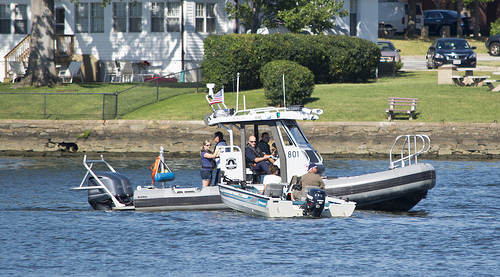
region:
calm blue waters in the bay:
[30, 217, 130, 243]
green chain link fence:
[51, 84, 142, 115]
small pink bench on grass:
[373, 83, 432, 118]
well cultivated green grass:
[333, 80, 393, 97]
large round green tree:
[257, 53, 318, 113]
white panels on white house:
[85, 29, 197, 66]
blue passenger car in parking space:
[419, 25, 479, 72]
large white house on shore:
[81, 2, 309, 86]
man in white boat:
[283, 150, 336, 200]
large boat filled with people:
[48, 90, 497, 244]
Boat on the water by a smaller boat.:
[72, 80, 436, 217]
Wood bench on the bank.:
[384, 91, 419, 119]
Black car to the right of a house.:
[426, 34, 476, 69]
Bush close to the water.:
[258, 56, 315, 113]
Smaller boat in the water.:
[216, 171, 356, 220]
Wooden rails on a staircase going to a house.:
[3, 31, 35, 80]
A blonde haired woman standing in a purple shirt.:
[197, 131, 217, 188]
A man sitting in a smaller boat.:
[285, 162, 326, 201]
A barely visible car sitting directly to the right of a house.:
[371, 36, 404, 68]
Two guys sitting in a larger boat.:
[243, 131, 280, 176]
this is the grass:
[424, 90, 473, 117]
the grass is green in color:
[425, 95, 477, 116]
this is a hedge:
[215, 30, 363, 87]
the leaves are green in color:
[260, 37, 338, 53]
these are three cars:
[383, 35, 499, 62]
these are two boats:
[58, 99, 430, 211]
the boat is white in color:
[291, 157, 301, 169]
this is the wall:
[114, 33, 187, 57]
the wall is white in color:
[131, 34, 181, 57]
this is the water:
[186, 222, 231, 274]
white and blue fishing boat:
[213, 170, 359, 228]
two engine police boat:
[74, 97, 459, 217]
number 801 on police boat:
[283, 141, 305, 161]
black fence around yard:
[8, 58, 200, 118]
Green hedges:
[203, 27, 385, 92]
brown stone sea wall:
[4, 115, 491, 160]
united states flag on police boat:
[197, 83, 317, 128]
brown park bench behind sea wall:
[373, 87, 438, 163]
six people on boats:
[179, 109, 432, 215]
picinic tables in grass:
[433, 62, 499, 108]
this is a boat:
[137, 120, 407, 216]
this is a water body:
[120, 217, 258, 258]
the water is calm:
[144, 216, 215, 261]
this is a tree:
[266, 54, 308, 94]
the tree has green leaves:
[287, 70, 300, 77]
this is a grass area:
[331, 80, 363, 113]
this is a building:
[93, 2, 196, 55]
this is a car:
[425, 36, 475, 66]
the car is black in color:
[441, 45, 473, 50]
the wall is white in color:
[122, 35, 170, 46]